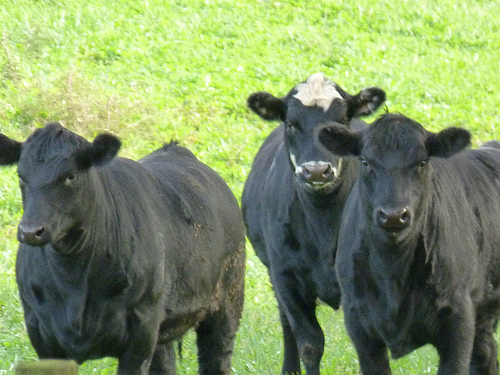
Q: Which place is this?
A: It is a field.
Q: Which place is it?
A: It is a field.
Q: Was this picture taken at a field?
A: Yes, it was taken in a field.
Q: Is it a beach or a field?
A: It is a field.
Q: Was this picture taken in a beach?
A: No, the picture was taken in a field.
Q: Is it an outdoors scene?
A: Yes, it is outdoors.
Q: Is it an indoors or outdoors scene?
A: It is outdoors.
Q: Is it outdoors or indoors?
A: It is outdoors.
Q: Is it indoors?
A: No, it is outdoors.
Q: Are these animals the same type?
A: Yes, all the animals are cows.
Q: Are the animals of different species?
A: No, all the animals are cows.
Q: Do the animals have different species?
A: No, all the animals are cows.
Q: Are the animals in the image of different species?
A: No, all the animals are cows.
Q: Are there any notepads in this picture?
A: No, there are no notepads.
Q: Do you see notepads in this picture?
A: No, there are no notepads.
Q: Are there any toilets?
A: No, there are no toilets.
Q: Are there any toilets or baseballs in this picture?
A: No, there are no toilets or baseballs.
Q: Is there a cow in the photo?
A: Yes, there is a cow.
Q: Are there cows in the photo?
A: Yes, there is a cow.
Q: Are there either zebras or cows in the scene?
A: Yes, there is a cow.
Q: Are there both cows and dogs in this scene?
A: No, there is a cow but no dogs.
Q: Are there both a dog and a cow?
A: No, there is a cow but no dogs.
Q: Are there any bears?
A: No, there are no bears.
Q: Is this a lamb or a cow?
A: This is a cow.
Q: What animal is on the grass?
A: The cow is on the grass.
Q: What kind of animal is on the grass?
A: The animal is a cow.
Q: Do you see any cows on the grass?
A: Yes, there is a cow on the grass.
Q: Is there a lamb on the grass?
A: No, there is a cow on the grass.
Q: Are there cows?
A: Yes, there is a cow.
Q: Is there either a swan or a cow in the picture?
A: Yes, there is a cow.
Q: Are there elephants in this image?
A: No, there are no elephants.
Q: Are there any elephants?
A: No, there are no elephants.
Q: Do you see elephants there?
A: No, there are no elephants.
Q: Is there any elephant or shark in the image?
A: No, there are no elephants or sharks.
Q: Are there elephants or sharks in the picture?
A: No, there are no elephants or sharks.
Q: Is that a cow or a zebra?
A: That is a cow.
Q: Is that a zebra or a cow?
A: That is a cow.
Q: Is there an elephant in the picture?
A: No, there are no elephants.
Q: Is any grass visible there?
A: Yes, there is grass.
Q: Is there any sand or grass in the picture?
A: Yes, there is grass.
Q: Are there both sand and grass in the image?
A: No, there is grass but no sand.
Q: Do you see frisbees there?
A: No, there are no frisbees.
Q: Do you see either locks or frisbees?
A: No, there are no frisbees or locks.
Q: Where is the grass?
A: The grass is in the field.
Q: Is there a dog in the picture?
A: No, there are no dogs.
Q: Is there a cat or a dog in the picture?
A: No, there are no dogs or cats.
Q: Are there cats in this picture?
A: No, there are no cats.